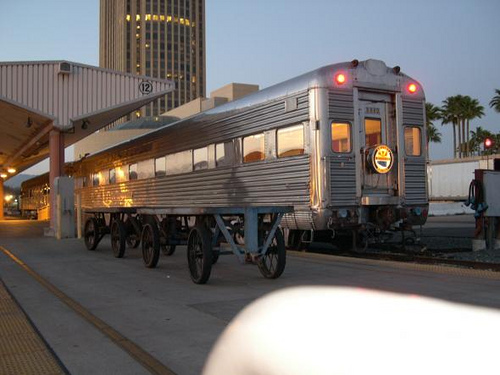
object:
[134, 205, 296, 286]
cart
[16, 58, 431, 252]
train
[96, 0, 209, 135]
building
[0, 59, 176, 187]
roofing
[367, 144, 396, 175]
object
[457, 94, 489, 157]
trees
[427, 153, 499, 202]
wall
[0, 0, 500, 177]
sky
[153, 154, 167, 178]
windows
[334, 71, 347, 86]
tail light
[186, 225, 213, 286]
wheel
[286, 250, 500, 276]
tracks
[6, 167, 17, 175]
lights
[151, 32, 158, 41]
windows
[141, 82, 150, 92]
12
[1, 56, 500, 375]
train station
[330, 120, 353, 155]
window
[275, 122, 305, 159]
window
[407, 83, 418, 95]
tail light